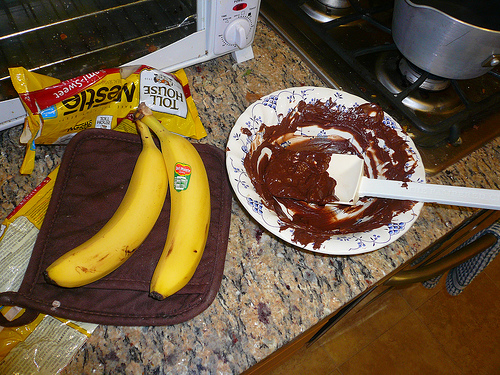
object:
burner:
[375, 51, 475, 116]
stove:
[257, 0, 499, 176]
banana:
[42, 109, 170, 288]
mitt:
[0, 125, 232, 328]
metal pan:
[389, 0, 500, 82]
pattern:
[261, 92, 280, 113]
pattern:
[387, 222, 407, 236]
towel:
[411, 219, 500, 298]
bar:
[382, 223, 500, 286]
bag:
[6, 64, 210, 145]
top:
[15, 114, 41, 176]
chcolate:
[6, 63, 209, 146]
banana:
[137, 104, 213, 300]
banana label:
[173, 162, 193, 193]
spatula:
[260, 147, 500, 212]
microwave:
[0, 0, 261, 135]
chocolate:
[236, 101, 424, 251]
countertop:
[0, 0, 500, 375]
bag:
[0, 158, 109, 375]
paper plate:
[222, 82, 430, 260]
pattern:
[245, 195, 266, 216]